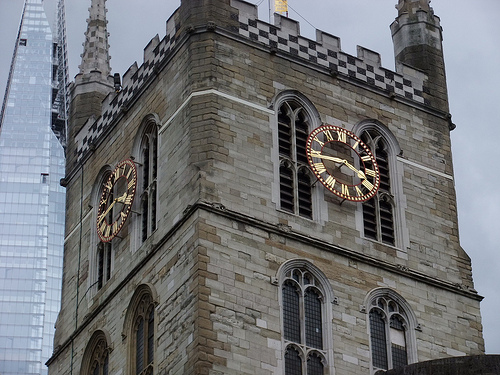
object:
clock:
[91, 120, 381, 243]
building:
[42, 2, 499, 373]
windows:
[82, 90, 418, 374]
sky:
[1, 4, 499, 334]